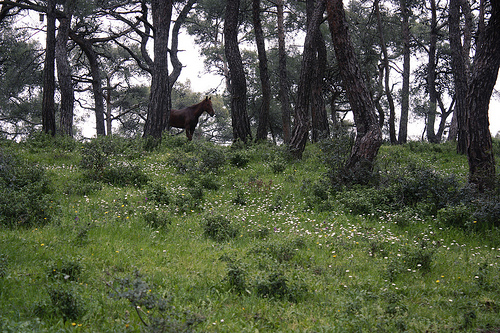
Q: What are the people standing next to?
A: A store.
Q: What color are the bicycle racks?
A: Gray.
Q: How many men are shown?
A: Zero.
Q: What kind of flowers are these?
A: Wildflowers.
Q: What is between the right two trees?
A: Brush.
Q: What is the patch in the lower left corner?
A: Grass.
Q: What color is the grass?
A: Green.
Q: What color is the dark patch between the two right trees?
A: Green.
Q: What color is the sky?
A: White.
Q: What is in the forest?
A: Horse.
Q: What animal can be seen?
A: Horse.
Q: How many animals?
A: One.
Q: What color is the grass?
A: Green.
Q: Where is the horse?
A: On a slope.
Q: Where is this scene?
A: The forest.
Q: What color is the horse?
A: Brown.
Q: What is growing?
A: White and yellow flowers.